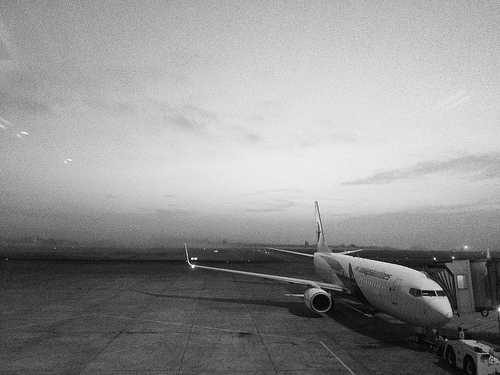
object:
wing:
[184, 242, 345, 291]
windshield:
[422, 290, 435, 295]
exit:
[417, 257, 500, 317]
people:
[411, 322, 427, 341]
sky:
[0, 0, 500, 259]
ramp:
[428, 254, 495, 316]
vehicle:
[439, 332, 500, 373]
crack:
[232, 277, 278, 375]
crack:
[178, 277, 205, 375]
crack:
[0, 369, 370, 374]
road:
[0, 264, 500, 362]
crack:
[77, 276, 180, 375]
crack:
[273, 285, 375, 373]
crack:
[49, 331, 322, 335]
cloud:
[0, 60, 499, 213]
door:
[389, 277, 402, 304]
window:
[409, 288, 415, 296]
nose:
[439, 303, 453, 329]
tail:
[265, 200, 364, 282]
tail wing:
[266, 247, 313, 258]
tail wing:
[340, 249, 365, 255]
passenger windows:
[340, 271, 382, 288]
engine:
[284, 287, 333, 314]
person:
[453, 326, 464, 338]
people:
[415, 329, 428, 346]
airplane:
[184, 200, 455, 352]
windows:
[415, 290, 420, 297]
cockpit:
[409, 276, 446, 297]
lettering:
[354, 265, 391, 280]